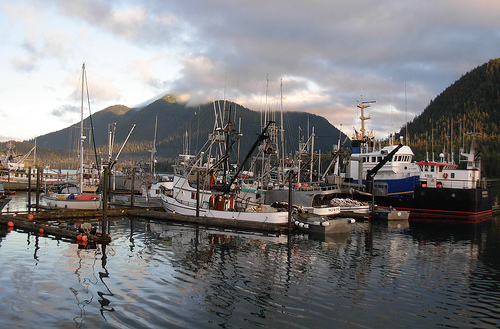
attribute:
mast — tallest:
[76, 62, 90, 192]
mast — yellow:
[347, 92, 395, 164]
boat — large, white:
[159, 174, 291, 230]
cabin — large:
[172, 176, 212, 206]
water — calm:
[30, 253, 456, 304]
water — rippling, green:
[0, 186, 499, 327]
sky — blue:
[17, 10, 154, 51]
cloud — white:
[170, 50, 268, 87]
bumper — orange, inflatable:
[4, 206, 106, 258]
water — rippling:
[2, 230, 497, 327]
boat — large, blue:
[333, 137, 423, 199]